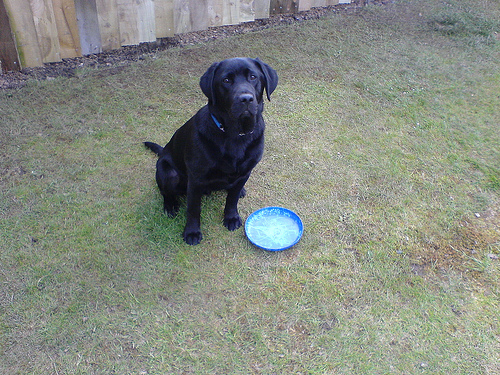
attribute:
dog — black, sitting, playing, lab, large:
[140, 54, 277, 244]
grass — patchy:
[1, 0, 498, 373]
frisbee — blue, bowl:
[244, 206, 303, 252]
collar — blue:
[207, 109, 254, 138]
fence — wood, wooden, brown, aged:
[0, 0, 355, 73]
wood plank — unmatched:
[73, 1, 103, 57]